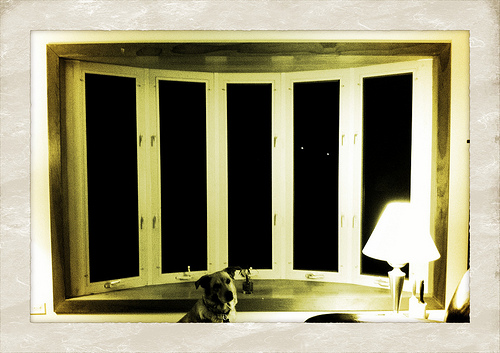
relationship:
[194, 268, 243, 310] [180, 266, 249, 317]
head of dog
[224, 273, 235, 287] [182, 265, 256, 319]
eye of dog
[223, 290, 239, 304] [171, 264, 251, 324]
nose of dog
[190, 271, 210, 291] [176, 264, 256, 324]
ear of dog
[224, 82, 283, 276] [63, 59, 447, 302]
window in room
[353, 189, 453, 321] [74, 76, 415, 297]
lamp in room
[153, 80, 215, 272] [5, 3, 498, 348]
window in room